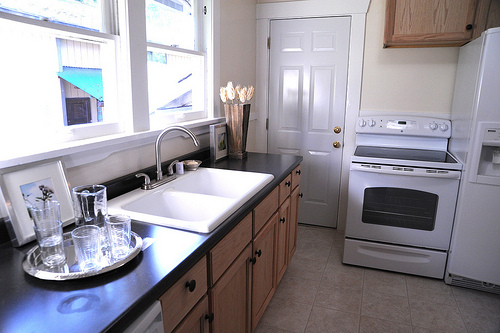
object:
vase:
[223, 102, 251, 157]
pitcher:
[0, 154, 80, 249]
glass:
[103, 213, 135, 257]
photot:
[0, 154, 76, 246]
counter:
[1, 148, 304, 332]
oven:
[341, 114, 464, 279]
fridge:
[443, 27, 499, 298]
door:
[267, 15, 353, 228]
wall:
[255, 0, 459, 232]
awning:
[57, 68, 106, 107]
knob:
[332, 141, 342, 149]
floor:
[254, 223, 499, 332]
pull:
[184, 279, 198, 291]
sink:
[97, 156, 274, 233]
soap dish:
[179, 157, 204, 171]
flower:
[225, 79, 237, 102]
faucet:
[154, 124, 201, 180]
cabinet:
[381, 0, 480, 47]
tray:
[18, 224, 145, 281]